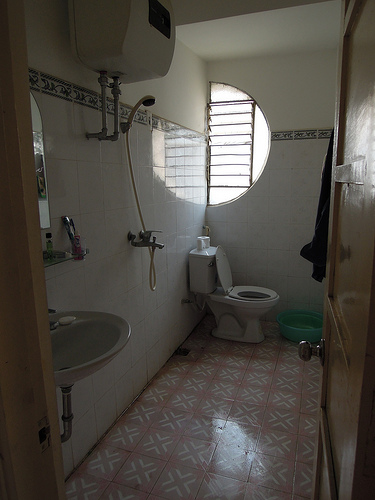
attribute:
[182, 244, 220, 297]
cistern — water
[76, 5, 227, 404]
shower — open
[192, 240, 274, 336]
tank — open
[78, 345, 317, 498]
bathroom floor — Bathroom 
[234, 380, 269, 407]
x pattern — x 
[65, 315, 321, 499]
tiled floor — White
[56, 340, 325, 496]
floor — tiled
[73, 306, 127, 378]
sink — Oval bathroom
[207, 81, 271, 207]
window — open, circle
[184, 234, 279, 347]
toilet —  white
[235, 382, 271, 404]
tile — pink, white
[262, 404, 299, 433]
tile — pink, white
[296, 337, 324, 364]
knob — silver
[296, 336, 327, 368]
knob — Silver door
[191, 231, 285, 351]
toilet — White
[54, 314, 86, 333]
soap — Bar 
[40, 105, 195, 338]
tiles — white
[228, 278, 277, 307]
seat — toilet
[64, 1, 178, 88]
bathroom fan — Large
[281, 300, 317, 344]
bowl — green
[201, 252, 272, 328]
toilet — White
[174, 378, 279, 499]
floor — pink and white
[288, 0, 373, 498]
door — Opened wooden, Open wooden bathroom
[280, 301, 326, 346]
tub — Green plastic 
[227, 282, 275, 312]
seat — down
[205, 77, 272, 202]
circle. — half 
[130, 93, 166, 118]
head — Shower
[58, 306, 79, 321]
soap — bar 